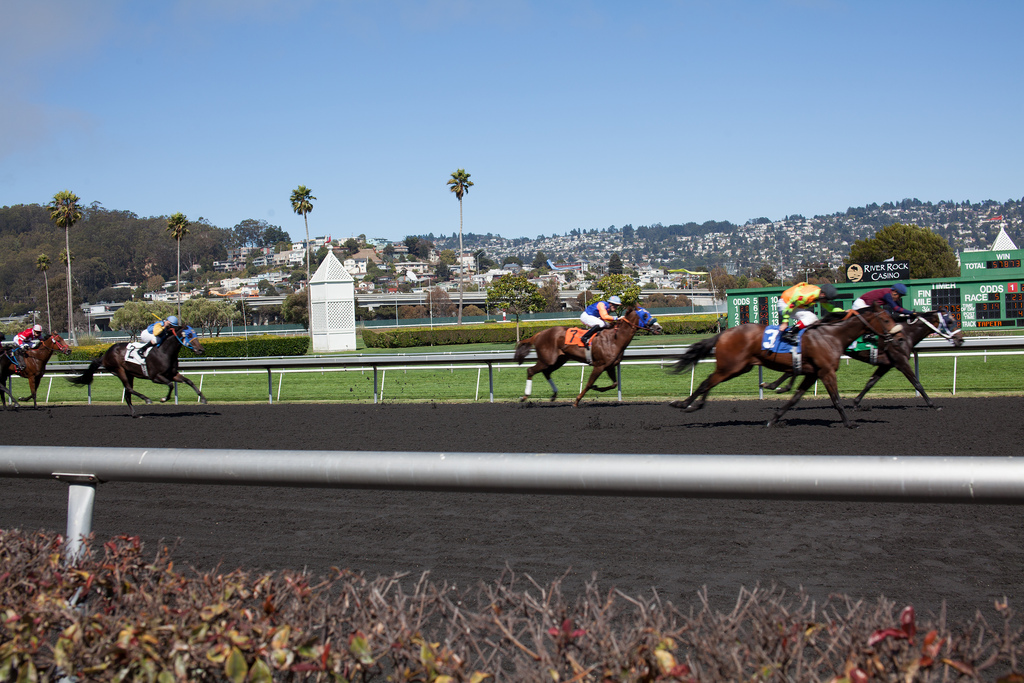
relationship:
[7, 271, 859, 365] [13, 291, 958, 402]
jockeys are on horses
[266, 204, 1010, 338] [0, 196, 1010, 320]
houses are on hill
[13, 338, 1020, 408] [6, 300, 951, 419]
guardrail near horses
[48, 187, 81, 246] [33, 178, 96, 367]
branch on trees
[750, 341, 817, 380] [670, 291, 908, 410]
number on horse